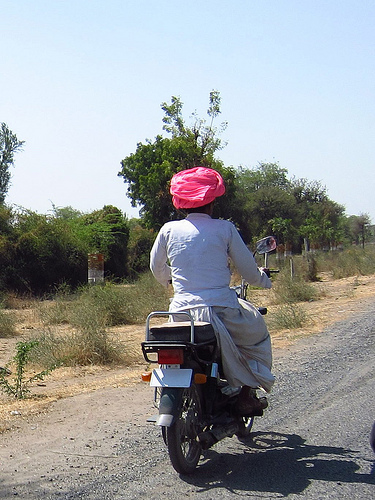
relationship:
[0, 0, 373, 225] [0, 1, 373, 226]
clouds in sky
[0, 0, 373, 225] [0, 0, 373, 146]
clouds in sky